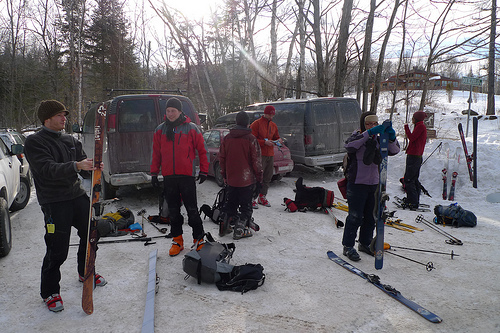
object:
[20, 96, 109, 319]
skier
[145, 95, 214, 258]
skier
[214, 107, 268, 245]
skier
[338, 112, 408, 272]
skier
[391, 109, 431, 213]
skiers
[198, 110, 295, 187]
vehicle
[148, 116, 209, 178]
jacket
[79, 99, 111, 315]
ski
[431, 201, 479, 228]
bag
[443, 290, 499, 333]
ground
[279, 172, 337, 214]
bag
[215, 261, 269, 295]
bag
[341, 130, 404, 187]
jacket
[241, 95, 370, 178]
van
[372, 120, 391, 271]
ski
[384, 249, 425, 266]
poles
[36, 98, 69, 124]
hat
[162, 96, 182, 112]
hat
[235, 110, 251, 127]
hat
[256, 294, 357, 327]
snow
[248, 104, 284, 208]
person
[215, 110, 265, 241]
person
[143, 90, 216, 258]
man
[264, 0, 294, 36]
branch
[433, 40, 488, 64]
branch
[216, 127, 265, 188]
jacket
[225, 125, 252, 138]
hood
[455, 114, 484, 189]
skis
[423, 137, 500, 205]
snowbank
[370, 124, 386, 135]
hands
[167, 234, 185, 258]
boots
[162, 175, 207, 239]
pants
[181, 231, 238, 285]
backpack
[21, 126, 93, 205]
jacket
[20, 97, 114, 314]
man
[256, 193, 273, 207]
boot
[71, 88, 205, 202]
van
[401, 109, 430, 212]
person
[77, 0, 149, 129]
tree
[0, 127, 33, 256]
vehicle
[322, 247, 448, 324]
ski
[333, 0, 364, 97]
tree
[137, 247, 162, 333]
ski equipment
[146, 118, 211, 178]
coat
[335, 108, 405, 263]
man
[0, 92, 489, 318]
lot